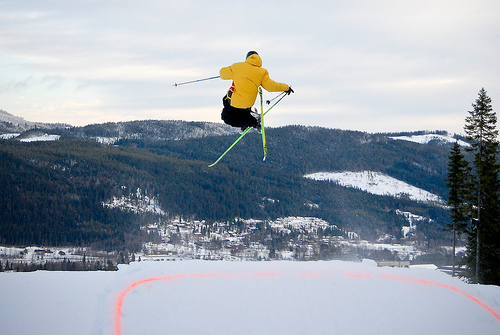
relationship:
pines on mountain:
[13, 161, 306, 237] [0, 110, 499, 233]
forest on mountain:
[18, 131, 392, 221] [26, 127, 499, 232]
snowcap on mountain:
[385, 118, 470, 155] [0, 110, 499, 233]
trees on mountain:
[446, 98, 495, 286] [0, 110, 499, 233]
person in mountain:
[187, 36, 292, 167] [26, 127, 499, 232]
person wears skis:
[220, 50, 295, 134] [205, 88, 292, 172]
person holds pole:
[220, 50, 295, 134] [173, 66, 238, 92]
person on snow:
[220, 50, 295, 134] [93, 248, 425, 333]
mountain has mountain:
[26, 127, 499, 232] [0, 110, 499, 233]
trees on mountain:
[446, 98, 495, 286] [26, 127, 499, 232]